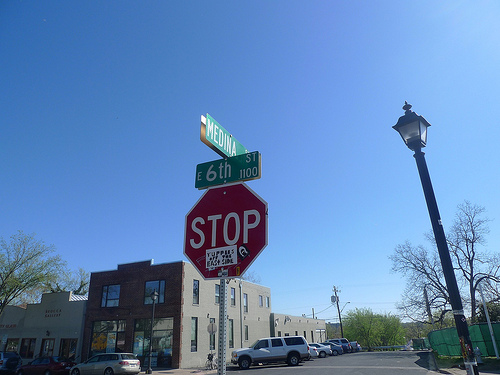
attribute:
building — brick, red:
[78, 259, 279, 372]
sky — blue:
[4, 0, 499, 323]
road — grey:
[174, 350, 451, 374]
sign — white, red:
[180, 179, 274, 283]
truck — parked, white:
[228, 334, 314, 369]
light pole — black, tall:
[390, 98, 487, 374]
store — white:
[3, 288, 92, 371]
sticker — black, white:
[201, 243, 242, 270]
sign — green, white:
[190, 148, 263, 191]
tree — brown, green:
[384, 202, 498, 336]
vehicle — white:
[308, 343, 321, 362]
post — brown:
[329, 283, 349, 339]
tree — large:
[0, 227, 63, 339]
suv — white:
[3, 348, 24, 374]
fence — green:
[419, 324, 499, 359]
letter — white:
[217, 160, 227, 181]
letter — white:
[245, 153, 253, 166]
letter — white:
[249, 149, 259, 163]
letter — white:
[196, 168, 204, 183]